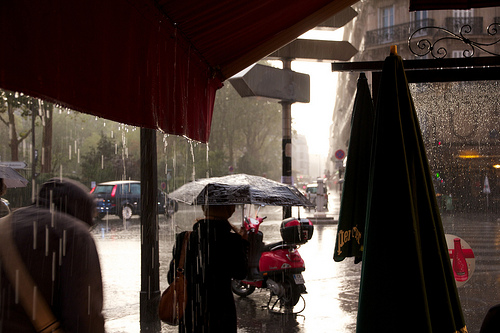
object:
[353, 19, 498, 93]
balcony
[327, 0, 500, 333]
building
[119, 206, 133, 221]
tire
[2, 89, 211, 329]
rain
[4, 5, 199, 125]
red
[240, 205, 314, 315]
motorbike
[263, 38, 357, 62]
sign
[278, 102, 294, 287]
pole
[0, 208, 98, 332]
person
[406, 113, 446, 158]
ground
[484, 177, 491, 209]
umbrella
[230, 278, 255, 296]
wheel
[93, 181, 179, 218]
car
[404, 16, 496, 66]
window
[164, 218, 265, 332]
coat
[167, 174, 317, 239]
umbrella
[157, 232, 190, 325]
purse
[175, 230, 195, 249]
shoulder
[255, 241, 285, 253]
seat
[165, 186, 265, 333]
lady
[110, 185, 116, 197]
tail lights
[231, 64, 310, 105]
sign